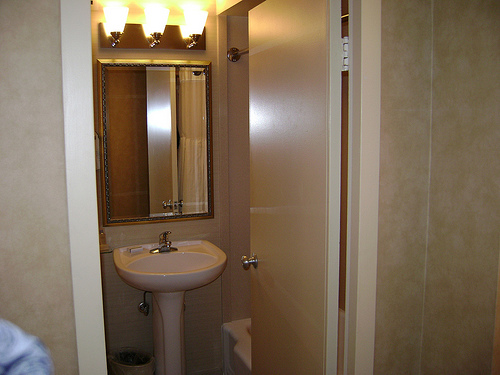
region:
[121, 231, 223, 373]
A tall white sink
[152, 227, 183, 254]
A metallic sink faucet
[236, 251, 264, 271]
A metal door knob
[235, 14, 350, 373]
A white door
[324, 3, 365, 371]
Gap between the door and the wall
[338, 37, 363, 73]
White door hinges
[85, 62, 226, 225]
Mirror above the sink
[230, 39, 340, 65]
Metal shower rod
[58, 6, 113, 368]
Wooden door frame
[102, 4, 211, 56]
Three lights above the mirror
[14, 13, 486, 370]
A bathroom scene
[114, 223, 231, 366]
This is the bathroom sink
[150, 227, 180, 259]
A water faucet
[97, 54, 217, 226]
A mirror is on the wall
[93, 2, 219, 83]
Lights are above the mirror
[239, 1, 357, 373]
The bathroom door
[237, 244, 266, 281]
A doorknob is on the door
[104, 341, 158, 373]
A wastebasket is under the sink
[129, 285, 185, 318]
The sink's plumbing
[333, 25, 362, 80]
A door hinge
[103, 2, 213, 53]
bathroom lights are on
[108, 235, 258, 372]
bathroom sink is white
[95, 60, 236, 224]
mirror above the sink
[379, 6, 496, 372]
the wall is brown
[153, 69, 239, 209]
reflection of door in mirror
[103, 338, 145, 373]
trash can next to sink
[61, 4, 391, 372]
the door frame is white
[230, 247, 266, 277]
knob on door is silver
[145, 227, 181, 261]
faucet on sink is silver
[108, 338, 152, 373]
trash bag inside trash can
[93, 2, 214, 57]
three illuminated vanity lights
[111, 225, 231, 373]
white porcelain sink with base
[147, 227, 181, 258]
chrome hardware on white sink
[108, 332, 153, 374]
trash can with bag in it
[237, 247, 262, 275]
chrome doorknob on white painted door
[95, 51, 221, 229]
mirror with gold detailed frame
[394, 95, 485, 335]
beige and white wallpaper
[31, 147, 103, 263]
painted whie door frame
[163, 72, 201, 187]
reflection of door and shower curtain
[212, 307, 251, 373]
corner of white porcelain bathtub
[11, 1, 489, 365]
Photo is looking into a bathroom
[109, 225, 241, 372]
White sink in the bathroom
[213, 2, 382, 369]
The door is open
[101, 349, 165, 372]
Trash can next to the sink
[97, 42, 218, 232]
Mirror hanging above the sink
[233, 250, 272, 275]
Silver handle on the door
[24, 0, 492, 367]
Nobody shown in the photo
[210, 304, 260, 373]
The tub is white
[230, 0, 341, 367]
The bathroom door is white